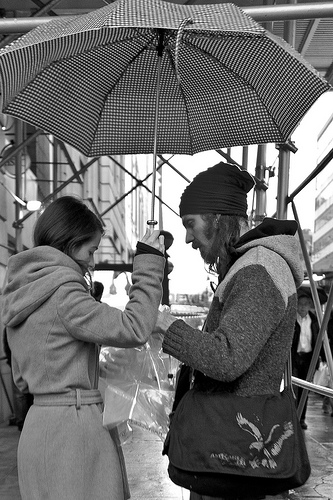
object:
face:
[182, 215, 211, 259]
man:
[152, 160, 305, 500]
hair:
[199, 214, 249, 271]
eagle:
[235, 410, 294, 471]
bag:
[101, 339, 178, 444]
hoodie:
[160, 217, 304, 400]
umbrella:
[0, 0, 333, 236]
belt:
[32, 388, 104, 408]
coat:
[0, 245, 167, 499]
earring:
[213, 225, 218, 233]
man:
[290, 294, 317, 431]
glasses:
[298, 301, 309, 307]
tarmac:
[12, 414, 324, 499]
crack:
[313, 473, 330, 496]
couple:
[0, 160, 313, 500]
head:
[178, 159, 249, 264]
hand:
[141, 226, 166, 256]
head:
[32, 196, 103, 276]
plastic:
[99, 320, 187, 425]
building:
[0, 113, 150, 423]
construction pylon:
[0, 0, 333, 424]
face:
[298, 297, 308, 315]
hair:
[31, 196, 105, 290]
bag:
[163, 348, 312, 494]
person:
[0, 197, 166, 500]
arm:
[166, 288, 278, 382]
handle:
[147, 219, 157, 233]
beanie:
[179, 159, 257, 217]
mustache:
[192, 242, 216, 264]